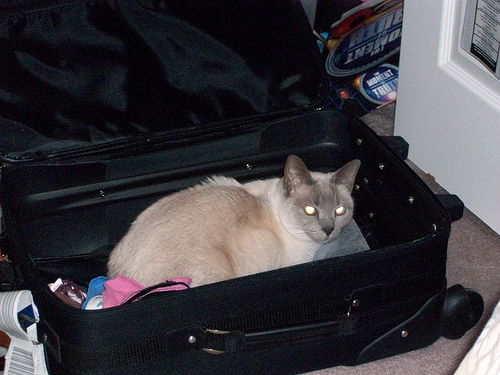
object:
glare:
[301, 203, 320, 218]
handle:
[202, 299, 363, 357]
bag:
[0, 0, 486, 374]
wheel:
[437, 282, 483, 342]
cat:
[94, 154, 370, 291]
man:
[333, 88, 379, 117]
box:
[326, 0, 404, 119]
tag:
[0, 287, 55, 374]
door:
[390, 0, 500, 236]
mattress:
[450, 297, 499, 374]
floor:
[278, 103, 499, 375]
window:
[456, 0, 500, 83]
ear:
[280, 153, 316, 193]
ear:
[327, 159, 364, 189]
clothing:
[99, 272, 191, 315]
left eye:
[333, 201, 347, 219]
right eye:
[302, 202, 318, 217]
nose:
[320, 226, 334, 233]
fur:
[160, 196, 256, 265]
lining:
[120, 279, 189, 303]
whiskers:
[282, 219, 311, 242]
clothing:
[81, 274, 112, 311]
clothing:
[44, 277, 87, 308]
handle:
[18, 311, 61, 360]